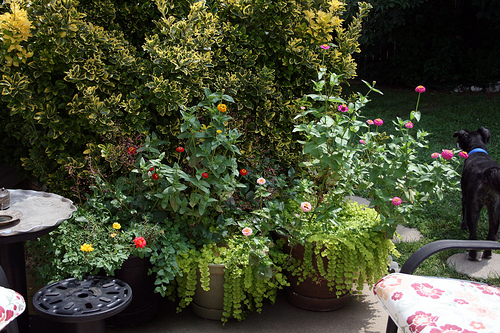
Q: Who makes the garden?
A: A gardener.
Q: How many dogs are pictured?
A: One.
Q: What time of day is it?
A: Morning.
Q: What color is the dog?
A: Black.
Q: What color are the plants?
A: Green.